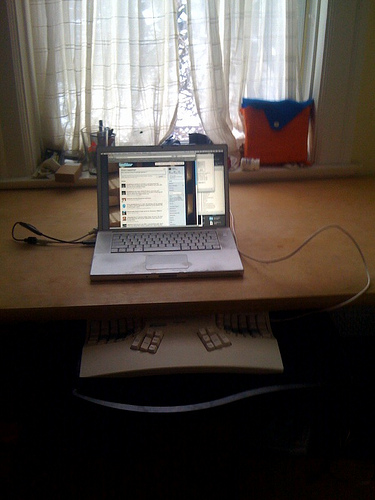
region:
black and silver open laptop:
[84, 138, 242, 277]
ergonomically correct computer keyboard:
[75, 306, 285, 381]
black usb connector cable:
[4, 216, 100, 252]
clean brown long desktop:
[0, 170, 369, 300]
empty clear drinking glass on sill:
[77, 117, 107, 172]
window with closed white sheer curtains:
[4, 0, 354, 183]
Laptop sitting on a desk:
[87, 141, 254, 286]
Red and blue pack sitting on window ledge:
[239, 95, 312, 183]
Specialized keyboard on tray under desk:
[73, 292, 292, 392]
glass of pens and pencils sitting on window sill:
[80, 120, 118, 191]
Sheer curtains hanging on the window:
[6, 2, 337, 177]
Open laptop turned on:
[84, 140, 244, 286]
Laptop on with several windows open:
[88, 142, 243, 285]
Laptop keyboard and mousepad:
[85, 222, 244, 278]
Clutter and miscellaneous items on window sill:
[30, 135, 316, 180]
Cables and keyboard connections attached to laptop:
[7, 210, 371, 319]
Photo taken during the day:
[10, 7, 363, 489]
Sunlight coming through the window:
[6, 2, 333, 178]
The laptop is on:
[57, 140, 265, 284]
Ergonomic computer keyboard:
[54, 312, 301, 381]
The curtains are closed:
[18, 3, 343, 167]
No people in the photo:
[4, 9, 368, 489]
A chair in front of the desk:
[1, 365, 343, 485]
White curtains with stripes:
[4, 14, 339, 166]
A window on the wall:
[0, 1, 336, 170]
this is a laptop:
[45, 120, 267, 296]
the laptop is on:
[83, 123, 259, 296]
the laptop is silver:
[68, 117, 248, 287]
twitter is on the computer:
[104, 154, 207, 230]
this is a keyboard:
[75, 289, 294, 393]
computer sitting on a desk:
[4, 133, 371, 318]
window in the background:
[6, 6, 363, 183]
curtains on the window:
[11, 4, 348, 162]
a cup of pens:
[59, 101, 122, 184]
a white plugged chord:
[244, 217, 372, 339]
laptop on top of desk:
[90, 139, 249, 283]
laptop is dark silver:
[88, 137, 247, 288]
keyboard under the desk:
[76, 304, 289, 388]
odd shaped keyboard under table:
[72, 297, 288, 382]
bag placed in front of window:
[234, 92, 315, 169]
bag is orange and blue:
[238, 95, 315, 168]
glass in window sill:
[77, 122, 112, 176]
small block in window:
[52, 159, 81, 182]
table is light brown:
[0, 175, 374, 325]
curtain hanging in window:
[15, 1, 307, 161]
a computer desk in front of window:
[20, 39, 350, 419]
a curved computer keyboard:
[81, 309, 308, 395]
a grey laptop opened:
[60, 114, 290, 314]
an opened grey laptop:
[51, 110, 294, 299]